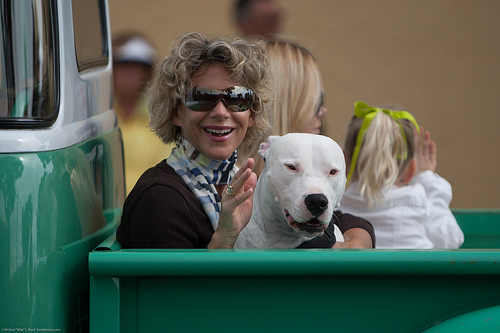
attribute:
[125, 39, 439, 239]
people — sitting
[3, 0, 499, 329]
truck — turquoise, green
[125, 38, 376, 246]
woman — smiling, waving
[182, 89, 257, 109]
sunglasses — reflective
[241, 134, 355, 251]
dog — white, sitting, riding, held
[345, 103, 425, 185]
ribbons — yellow, tied, green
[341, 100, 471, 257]
girl — waving, held, blonde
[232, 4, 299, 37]
man — standing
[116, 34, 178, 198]
man — standing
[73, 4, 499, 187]
background — hazy brown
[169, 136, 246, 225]
scarf — checkered, colorful, striped, wrapped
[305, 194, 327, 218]
nose — black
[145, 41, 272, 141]
hair — blonde, burly, curly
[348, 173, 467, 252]
coat — white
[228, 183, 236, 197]
ring — worn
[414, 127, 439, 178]
hand — up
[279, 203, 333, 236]
mouth — open